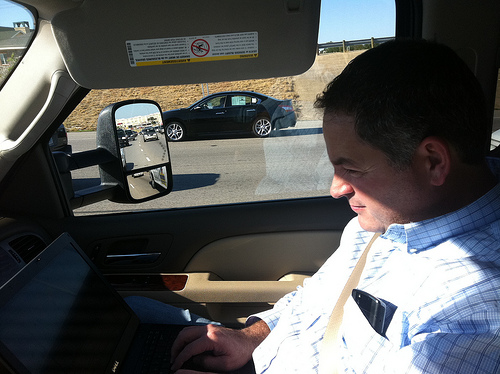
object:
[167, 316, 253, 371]
hand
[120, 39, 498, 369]
man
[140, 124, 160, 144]
car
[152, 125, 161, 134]
car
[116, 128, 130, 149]
car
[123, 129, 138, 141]
car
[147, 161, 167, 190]
car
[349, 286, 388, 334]
cell phone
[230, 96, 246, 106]
paper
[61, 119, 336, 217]
street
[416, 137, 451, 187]
ear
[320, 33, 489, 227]
head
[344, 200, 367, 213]
mouth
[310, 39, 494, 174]
hair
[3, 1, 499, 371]
truck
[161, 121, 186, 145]
wheel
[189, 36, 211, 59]
symbol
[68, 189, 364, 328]
door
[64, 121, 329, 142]
curb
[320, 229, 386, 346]
belt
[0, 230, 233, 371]
laptop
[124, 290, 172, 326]
lap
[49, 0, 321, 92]
visor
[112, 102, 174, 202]
side mirror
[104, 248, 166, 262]
handle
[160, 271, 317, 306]
arm rest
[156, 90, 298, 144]
car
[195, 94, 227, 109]
window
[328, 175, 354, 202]
nose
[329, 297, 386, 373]
pocket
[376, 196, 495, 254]
collar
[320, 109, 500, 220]
shadow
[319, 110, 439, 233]
face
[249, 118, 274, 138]
back tire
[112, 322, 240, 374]
laptop keyboard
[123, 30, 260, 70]
tag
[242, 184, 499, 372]
shirt